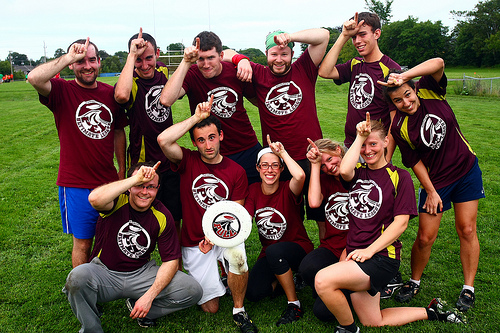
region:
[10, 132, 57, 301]
The grass is short and green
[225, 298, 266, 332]
The shoe of the man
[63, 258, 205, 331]
The man has on pants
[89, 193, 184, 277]
The man has on a maroon shirt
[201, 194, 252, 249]
The man is holding a frisbee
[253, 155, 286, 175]
The woman has on a pair of glasses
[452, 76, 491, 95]
The gate is made of metal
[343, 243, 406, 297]
The girl has on black shirts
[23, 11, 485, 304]
A group of people standing together posing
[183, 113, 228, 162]
The head of the man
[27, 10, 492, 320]
a team of a frisbee players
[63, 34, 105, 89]
a man with his hand on his head making the number one sign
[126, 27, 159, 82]
a man with his hand on his head making the number one sign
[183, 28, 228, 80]
a man with his hand on his head making the number one sign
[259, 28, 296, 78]
a man with his hand on his head making the number one sign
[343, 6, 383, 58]
a man with his hand on his head making the number one sign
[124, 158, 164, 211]
a man with his hand on his head making the number one sign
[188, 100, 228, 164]
a man with his hand on his head making the number one sign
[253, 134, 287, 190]
a woman with his hand on his head making the number one sign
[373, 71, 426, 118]
a woman with his hand on his head making the number one sign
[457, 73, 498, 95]
part of a chain link fence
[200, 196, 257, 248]
a large white Frisbee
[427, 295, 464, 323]
a woman's shoe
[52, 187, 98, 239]
part of a man's blue shorts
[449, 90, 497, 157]
a section of green grass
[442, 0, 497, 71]
part of a large green tree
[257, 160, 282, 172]
a woman's eyeglasses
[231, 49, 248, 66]
a red wristband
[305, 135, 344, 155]
part of a girl's hair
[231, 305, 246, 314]
a man's white sock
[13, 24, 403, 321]
People on the grass.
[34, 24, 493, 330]
Team on the grass.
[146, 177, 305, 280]
White frisbee in the man's hand.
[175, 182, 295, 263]
White, red, black frisbee.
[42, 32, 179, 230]
Red shirt on the man.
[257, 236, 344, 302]
Dark pants on the man.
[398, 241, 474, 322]
Tennis shoes on the man.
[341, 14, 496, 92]
Trees in the background.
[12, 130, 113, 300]
Green grass on the ground.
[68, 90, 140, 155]
White logo on the shirt.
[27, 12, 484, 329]
a team posing for a photo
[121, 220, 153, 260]
a white logo on a burgundy t-shirt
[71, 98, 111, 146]
a white logo on a burgundy t-shirt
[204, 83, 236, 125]
a white logo on a burgundy t-shirt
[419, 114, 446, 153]
a white logo on a burgundy t-shirt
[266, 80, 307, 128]
a white logo on a burgundy t-shirt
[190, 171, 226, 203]
a white logo on a burgundy t-shirt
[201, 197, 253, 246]
a white plastic frisbee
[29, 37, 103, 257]
a man wearing blue shorts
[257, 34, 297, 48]
a green scarf on a head